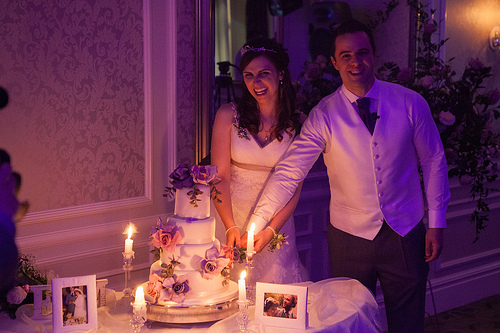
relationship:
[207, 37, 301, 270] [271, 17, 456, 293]
bride with groom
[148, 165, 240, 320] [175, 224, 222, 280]
cake has frosting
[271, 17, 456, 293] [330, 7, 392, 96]
man has a head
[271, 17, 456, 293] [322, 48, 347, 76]
man has an ear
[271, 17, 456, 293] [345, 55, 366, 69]
man has a nose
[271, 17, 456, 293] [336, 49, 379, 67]
man has eyes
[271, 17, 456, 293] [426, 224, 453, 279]
man has a hand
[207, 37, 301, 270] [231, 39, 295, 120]
woman has a head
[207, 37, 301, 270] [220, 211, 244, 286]
woman has a hand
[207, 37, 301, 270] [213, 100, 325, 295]
woman wears a wedding dress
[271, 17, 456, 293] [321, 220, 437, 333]
man wearing pants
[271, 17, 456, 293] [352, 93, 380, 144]
man wears a tie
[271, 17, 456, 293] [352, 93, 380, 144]
man has a tie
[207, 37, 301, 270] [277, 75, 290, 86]
woman has earring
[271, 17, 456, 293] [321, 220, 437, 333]
man has on pants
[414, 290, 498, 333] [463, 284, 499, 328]
carpet has a part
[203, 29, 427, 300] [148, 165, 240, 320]
couple cuts cake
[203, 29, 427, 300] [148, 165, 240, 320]
couple cutting cake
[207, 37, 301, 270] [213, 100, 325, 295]
woman wears wedding dress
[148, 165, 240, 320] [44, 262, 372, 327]
cake on table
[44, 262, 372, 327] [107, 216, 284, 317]
table has candles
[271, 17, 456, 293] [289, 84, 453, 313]
man has on a suit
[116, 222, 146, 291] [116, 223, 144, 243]
candle has flame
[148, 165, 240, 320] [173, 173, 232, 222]
cake has top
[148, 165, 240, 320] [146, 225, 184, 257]
cake has rose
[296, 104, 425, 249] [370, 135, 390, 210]
vest has buttons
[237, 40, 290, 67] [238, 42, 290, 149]
headband in hair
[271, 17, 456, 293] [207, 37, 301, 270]
man next to woman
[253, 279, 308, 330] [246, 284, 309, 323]
picture has frame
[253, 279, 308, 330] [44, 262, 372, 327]
picture sitting on table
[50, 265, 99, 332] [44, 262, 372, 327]
picture sitting on table